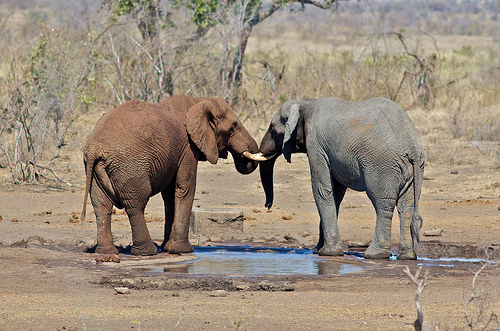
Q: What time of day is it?
A: Daytime.